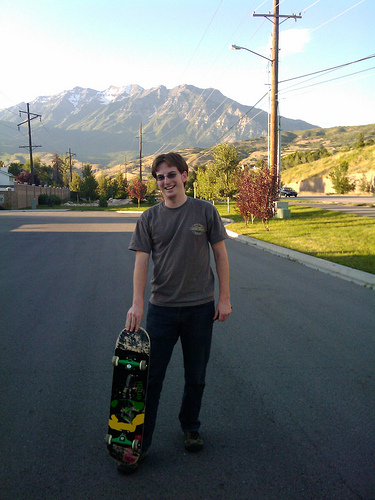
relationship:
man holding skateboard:
[118, 152, 233, 475] [105, 328, 151, 468]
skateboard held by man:
[105, 328, 151, 468] [118, 152, 233, 475]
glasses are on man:
[155, 171, 180, 182] [118, 152, 233, 475]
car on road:
[279, 186, 298, 199] [278, 189, 375, 215]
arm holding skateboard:
[124, 214, 151, 333] [105, 328, 151, 468]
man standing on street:
[118, 152, 233, 475] [2, 206, 374, 499]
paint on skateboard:
[108, 413, 144, 434] [105, 328, 151, 468]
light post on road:
[231, 43, 281, 196] [278, 189, 375, 215]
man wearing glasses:
[118, 152, 233, 475] [155, 171, 180, 182]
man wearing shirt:
[118, 152, 233, 475] [128, 197, 226, 307]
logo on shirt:
[188, 222, 207, 238] [128, 197, 226, 307]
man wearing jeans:
[118, 152, 233, 475] [141, 298, 215, 448]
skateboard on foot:
[105, 328, 151, 468] [115, 448, 149, 475]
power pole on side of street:
[251, 1, 303, 201] [2, 206, 374, 499]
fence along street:
[1, 179, 70, 212] [2, 206, 374, 499]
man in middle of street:
[118, 152, 233, 475] [2, 206, 374, 499]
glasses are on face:
[155, 171, 180, 182] [155, 167, 184, 199]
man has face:
[118, 152, 233, 475] [155, 167, 184, 199]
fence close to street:
[1, 179, 70, 212] [2, 206, 374, 499]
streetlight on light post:
[228, 43, 243, 54] [231, 43, 281, 196]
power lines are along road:
[139, 2, 374, 154] [278, 189, 375, 215]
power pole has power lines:
[251, 1, 303, 201] [139, 2, 374, 154]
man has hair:
[118, 152, 233, 475] [151, 153, 188, 181]